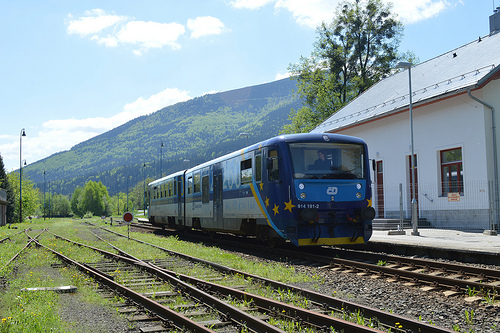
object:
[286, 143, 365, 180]
window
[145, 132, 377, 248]
vehicle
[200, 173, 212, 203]
window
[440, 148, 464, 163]
window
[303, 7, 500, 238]
building